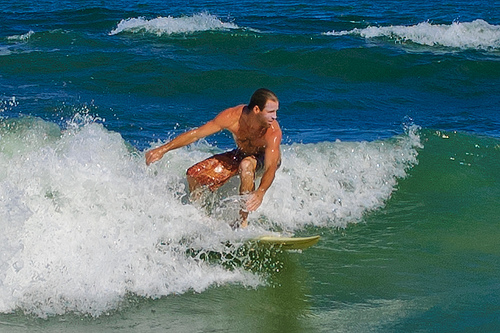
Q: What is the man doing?
A: Surfing.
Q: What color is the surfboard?
A: White.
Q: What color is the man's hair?
A: Brown.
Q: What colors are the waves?
A: Blue and grean.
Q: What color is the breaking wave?
A: White.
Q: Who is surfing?
A: A man.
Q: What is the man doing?
A: Surfing.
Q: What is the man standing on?
A: A surfboard.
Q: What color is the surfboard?
A: Yellow.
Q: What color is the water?
A: Blue and green.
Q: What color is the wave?
A: White.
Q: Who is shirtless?
A: The man on the surfboard.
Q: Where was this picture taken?
A: The ocean.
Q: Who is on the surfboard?
A: The man.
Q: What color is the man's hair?
A: Brown.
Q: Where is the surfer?
A: On the water.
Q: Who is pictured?
A: A man the is surfing.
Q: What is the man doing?
A: He is riding a surfboard.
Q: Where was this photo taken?
A: In the ocean.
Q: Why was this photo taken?
A: To capture the sport.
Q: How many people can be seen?
A: Just 1 man.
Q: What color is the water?
A: It is a greenish blue.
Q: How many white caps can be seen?
A: There are 3.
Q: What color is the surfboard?
A: It is yellow.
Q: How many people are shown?
A: One.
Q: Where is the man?
A: On a surfboard.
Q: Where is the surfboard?
A: In the water.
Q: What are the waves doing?
A: Splashing.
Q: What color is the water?
A: Blue and green.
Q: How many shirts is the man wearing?
A: None.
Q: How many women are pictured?
A: Zero.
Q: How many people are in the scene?
A: One.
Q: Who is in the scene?
A: A man.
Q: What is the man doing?
A: Surfing.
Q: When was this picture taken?
A: Daytime.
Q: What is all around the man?
A: Water.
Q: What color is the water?
A: Blue, green and white.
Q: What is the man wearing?
A: Shorts.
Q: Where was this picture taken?
A: Water.